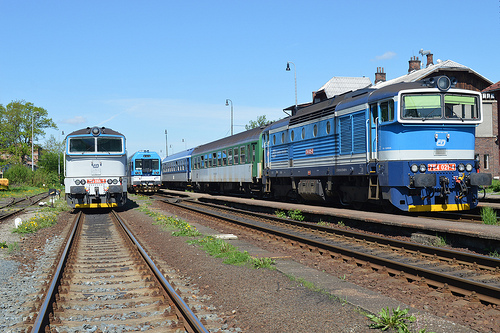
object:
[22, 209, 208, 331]
train tracks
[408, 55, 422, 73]
chimney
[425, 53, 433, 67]
chimney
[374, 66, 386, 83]
chimney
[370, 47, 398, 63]
clouds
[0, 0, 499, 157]
blue sky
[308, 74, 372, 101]
statue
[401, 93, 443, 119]
window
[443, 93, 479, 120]
window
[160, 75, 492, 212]
train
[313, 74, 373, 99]
roof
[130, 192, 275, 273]
grass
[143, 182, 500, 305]
tracks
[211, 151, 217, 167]
windows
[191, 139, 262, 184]
side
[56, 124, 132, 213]
train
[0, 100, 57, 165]
tree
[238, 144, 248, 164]
windows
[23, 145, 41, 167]
building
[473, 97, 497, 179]
wall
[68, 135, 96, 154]
windows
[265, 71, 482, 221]
train engine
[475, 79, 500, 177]
building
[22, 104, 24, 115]
leaves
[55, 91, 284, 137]
cloud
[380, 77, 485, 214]
front